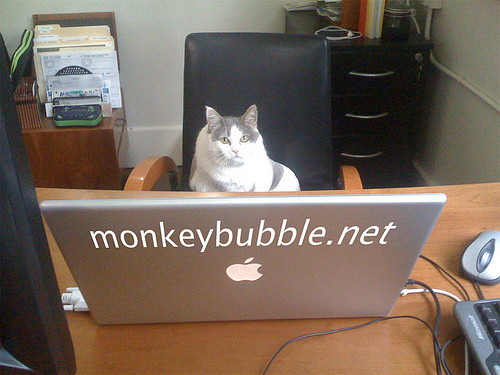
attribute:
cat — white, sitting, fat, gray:
[179, 100, 304, 190]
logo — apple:
[222, 254, 265, 287]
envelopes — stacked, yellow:
[30, 22, 124, 130]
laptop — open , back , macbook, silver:
[36, 193, 455, 336]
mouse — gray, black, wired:
[460, 223, 498, 286]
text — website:
[81, 221, 395, 253]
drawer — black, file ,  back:
[323, 23, 433, 167]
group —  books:
[345, 0, 389, 41]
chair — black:
[122, 23, 365, 191]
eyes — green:
[213, 129, 255, 149]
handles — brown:
[336, 154, 372, 187]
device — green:
[46, 95, 110, 130]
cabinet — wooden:
[18, 126, 132, 190]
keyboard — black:
[450, 285, 498, 372]